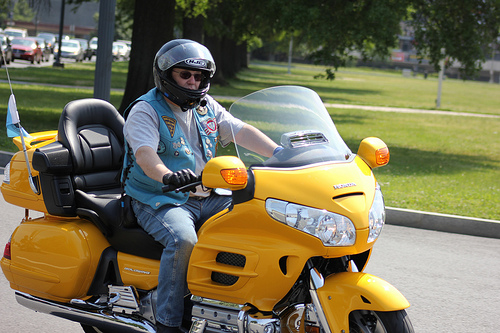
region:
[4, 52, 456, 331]
a yellow motorcycle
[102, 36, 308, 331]
man on a motorcycle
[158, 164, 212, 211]
black glove on hand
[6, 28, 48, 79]
a red car on street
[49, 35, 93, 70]
a silver car on street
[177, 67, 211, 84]
glasses on man's face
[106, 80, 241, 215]
a blue vest with patches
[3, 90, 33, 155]
a blue and white flag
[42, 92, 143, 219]
a black passenger seat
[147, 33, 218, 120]
a black helmet on head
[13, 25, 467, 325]
a motorcyle rider on the street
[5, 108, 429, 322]
this motorcyle is yellow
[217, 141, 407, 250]
this motorcyle has four lights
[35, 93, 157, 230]
there is a backseat for an extra rider\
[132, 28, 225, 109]
this is a motorcycle helmet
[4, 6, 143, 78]
traffic in the background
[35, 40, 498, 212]
this might be a park area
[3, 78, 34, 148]
the motorcycle rider has a blue flag on his bike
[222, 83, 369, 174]
this motorcylce has a windshield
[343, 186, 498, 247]
this is a part of the curb next to the street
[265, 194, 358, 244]
the headlight of a motorcycle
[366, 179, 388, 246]
the headlight of a motorcycle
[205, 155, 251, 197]
a rear view mirror with turn a signal light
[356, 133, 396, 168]
a rear view mirror with turn a signal light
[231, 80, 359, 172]
a windshield of a motorcycle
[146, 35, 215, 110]
a black motorcycle helmet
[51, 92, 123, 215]
a black seat of a motorcycle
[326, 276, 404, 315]
the fender of a motorcycle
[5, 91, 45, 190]
a flag on a motorcycle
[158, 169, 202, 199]
a hand on the handle bar of a motorcycle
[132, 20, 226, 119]
a man wearing a helmet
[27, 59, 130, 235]
an empty motorcycle seat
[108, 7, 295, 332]
an older man on a motorcycle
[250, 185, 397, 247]
headlights on the motorcycle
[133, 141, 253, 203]
a mans arm on the handle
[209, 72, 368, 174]
a motorcycle windshield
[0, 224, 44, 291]
brakelight of the yellow motorcycle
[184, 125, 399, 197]
two turn signal lights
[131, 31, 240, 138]
a motorcyclist wearing sunglasses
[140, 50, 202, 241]
this is a man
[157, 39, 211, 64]
this is a helmet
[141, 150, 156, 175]
the man is light skinned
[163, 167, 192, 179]
this is the glove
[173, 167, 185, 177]
the glove is black in color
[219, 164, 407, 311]
this is a motorbike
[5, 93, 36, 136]
this is a flag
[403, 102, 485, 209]
this is grass area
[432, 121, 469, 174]
the grass is green in color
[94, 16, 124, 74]
this is a pole